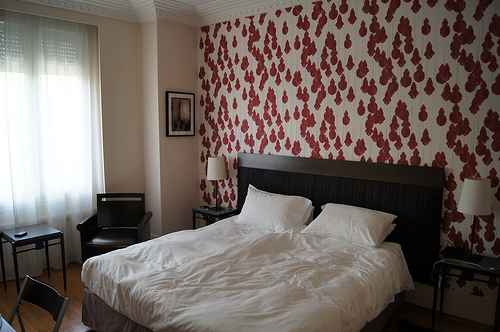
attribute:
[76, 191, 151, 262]
chair — brown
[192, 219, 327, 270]
spread — white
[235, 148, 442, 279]
headboard — black, brown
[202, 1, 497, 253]
wall paper — dotted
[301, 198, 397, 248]
pillow — white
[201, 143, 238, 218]
lamp — small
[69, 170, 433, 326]
spread — white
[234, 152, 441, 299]
headboard — wooden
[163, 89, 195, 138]
art — black, framed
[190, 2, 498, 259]
wallpaper — red, white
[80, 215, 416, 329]
sheets — white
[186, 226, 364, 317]
spread — white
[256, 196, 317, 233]
pillow — white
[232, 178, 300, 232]
pillow — white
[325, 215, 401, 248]
pillow — white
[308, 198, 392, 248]
pillow — white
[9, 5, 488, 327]
room — uncleaned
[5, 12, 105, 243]
curtains — white, sheer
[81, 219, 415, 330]
spread — white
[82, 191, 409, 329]
spread — white